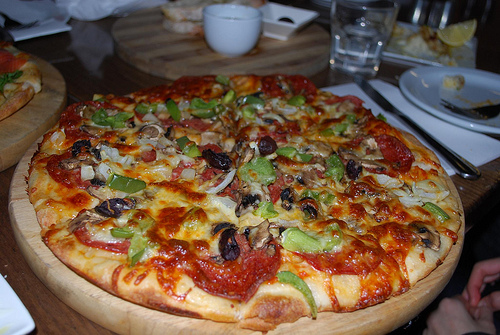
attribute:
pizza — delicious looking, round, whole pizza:
[27, 77, 464, 334]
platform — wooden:
[6, 122, 463, 335]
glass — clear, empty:
[328, 3, 400, 78]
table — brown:
[0, 3, 499, 335]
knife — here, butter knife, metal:
[354, 75, 482, 180]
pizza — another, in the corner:
[2, 40, 41, 120]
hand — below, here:
[422, 298, 495, 333]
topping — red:
[375, 135, 413, 170]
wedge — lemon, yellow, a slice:
[435, 19, 477, 48]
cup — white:
[65, 0, 128, 21]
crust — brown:
[29, 129, 310, 334]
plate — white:
[399, 67, 499, 135]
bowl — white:
[202, 5, 262, 59]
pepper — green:
[190, 97, 214, 118]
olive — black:
[299, 196, 315, 205]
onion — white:
[207, 167, 238, 195]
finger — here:
[468, 259, 496, 306]